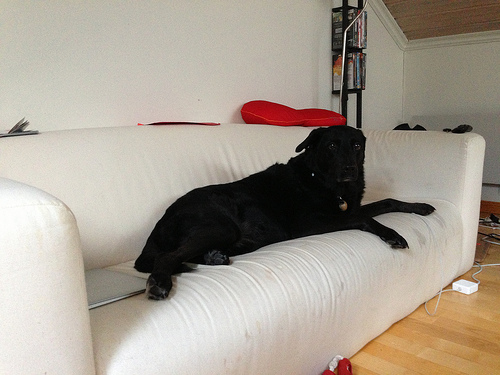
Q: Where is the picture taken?
A: A living room.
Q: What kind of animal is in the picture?
A: A dog.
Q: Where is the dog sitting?
A: On the couch.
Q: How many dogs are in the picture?
A: One.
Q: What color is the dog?
A: Black.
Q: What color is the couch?
A: White.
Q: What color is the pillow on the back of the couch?
A: Red.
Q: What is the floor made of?
A: Wood.